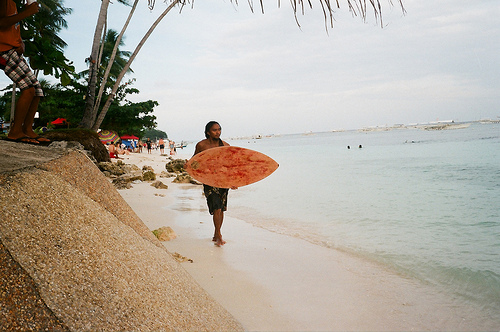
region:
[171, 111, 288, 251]
person carrying a surfboard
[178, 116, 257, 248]
person walking down the beach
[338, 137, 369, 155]
two people in the water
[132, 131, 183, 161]
people standing on the beach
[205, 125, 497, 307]
light blue body of water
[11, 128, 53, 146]
black sandals on the feet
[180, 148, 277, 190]
orange surfboard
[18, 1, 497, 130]
clouds in the sky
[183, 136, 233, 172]
no shirt on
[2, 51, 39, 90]
plaid shorts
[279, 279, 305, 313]
part of a shore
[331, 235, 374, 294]
edge of a shore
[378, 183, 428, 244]
part of a water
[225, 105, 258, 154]
part of a board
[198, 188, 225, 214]
part of a short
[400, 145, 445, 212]
part of a water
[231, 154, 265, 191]
edge of a board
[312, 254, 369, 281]
part of the ocean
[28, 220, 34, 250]
part of a rock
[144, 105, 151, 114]
part of a leaf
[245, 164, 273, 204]
part of a board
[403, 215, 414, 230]
part of the sea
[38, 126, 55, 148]
foot of a man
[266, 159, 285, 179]
tip of a board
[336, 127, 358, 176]
head of a man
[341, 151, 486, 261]
The water on the beach is clear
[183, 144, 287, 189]
The man is holding a surfboard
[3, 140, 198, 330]
A large boulder that is flat on top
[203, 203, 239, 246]
The leg's on the surfer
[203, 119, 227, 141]
The head of the surfer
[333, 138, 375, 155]
The swimmer's are all the way in the water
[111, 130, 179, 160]
A group of people standing on the beach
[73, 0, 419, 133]
The palm tree brings shade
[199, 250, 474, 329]
The sand on the beach is light brown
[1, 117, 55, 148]
The feet of the man on the boulder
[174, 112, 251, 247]
The person is holding a surfboard.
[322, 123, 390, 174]
People in the water.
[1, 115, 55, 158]
The person is wearing flip flops.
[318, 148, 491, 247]
The water is blue and calm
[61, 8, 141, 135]
Palm trees on the beach.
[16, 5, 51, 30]
The person is holding a cup in hand.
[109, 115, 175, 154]
People walking on the beach.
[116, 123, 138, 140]
Red umbrella on the beach.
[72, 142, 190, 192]
Big rocks on the beach.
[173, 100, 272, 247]
The person is walking through the sand.